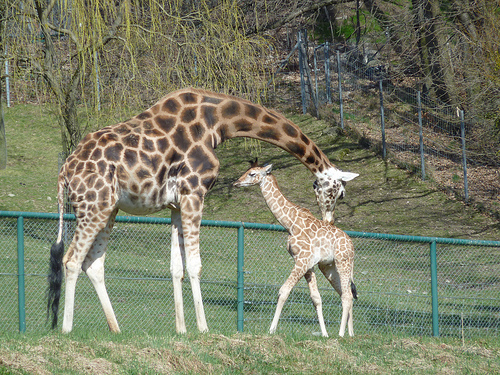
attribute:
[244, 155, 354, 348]
giraffe — young, small, walking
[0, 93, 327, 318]
giraffe — adult, tall, grooming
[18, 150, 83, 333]
tail — long, brown, black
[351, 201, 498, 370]
fence — green, metal, chainlink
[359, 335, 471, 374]
field — grassy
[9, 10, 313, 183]
tree — large, small, green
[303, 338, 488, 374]
grass — brown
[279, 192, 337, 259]
spots — brown, black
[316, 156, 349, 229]
face — black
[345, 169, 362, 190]
ear — white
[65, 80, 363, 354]
giraffes — spotted